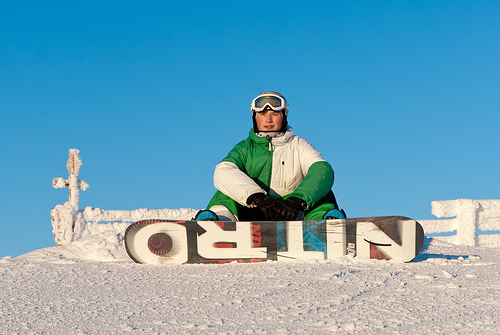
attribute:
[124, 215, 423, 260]
colored snowboard — multi colored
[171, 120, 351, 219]
snow suit — green , white 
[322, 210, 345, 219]
boots — black, blue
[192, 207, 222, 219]
boots — black, blue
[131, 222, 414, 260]
letters — white